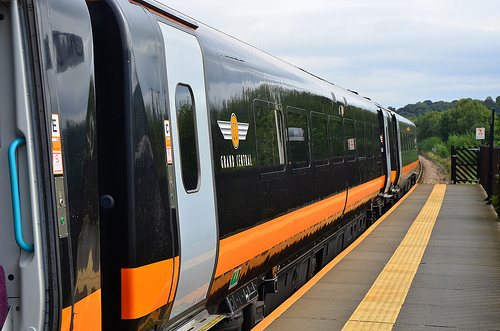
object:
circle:
[230, 112, 239, 150]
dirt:
[420, 152, 442, 184]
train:
[0, 0, 418, 328]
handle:
[9, 136, 34, 252]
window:
[174, 81, 204, 194]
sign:
[163, 120, 174, 165]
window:
[253, 100, 284, 165]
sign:
[475, 127, 485, 139]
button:
[60, 217, 65, 224]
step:
[164, 308, 227, 331]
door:
[158, 21, 218, 320]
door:
[1, 1, 61, 331]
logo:
[216, 112, 250, 150]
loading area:
[247, 183, 500, 329]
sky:
[152, 1, 498, 110]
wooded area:
[397, 96, 500, 157]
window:
[285, 111, 310, 168]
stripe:
[60, 161, 420, 331]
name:
[220, 155, 252, 169]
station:
[251, 182, 496, 329]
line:
[334, 183, 451, 331]